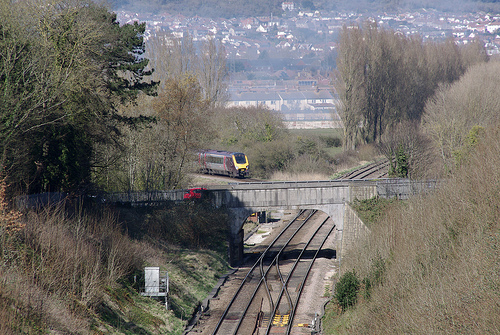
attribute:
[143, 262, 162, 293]
box — silver, metal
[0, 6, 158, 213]
trees — green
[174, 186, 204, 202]
train — red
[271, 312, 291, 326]
tool — yellow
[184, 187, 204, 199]
paint — red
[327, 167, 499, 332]
grass — tall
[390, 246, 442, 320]
plants — dried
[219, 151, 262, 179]
train — yellow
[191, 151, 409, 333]
railway — line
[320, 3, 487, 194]
trees — dead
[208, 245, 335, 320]
railway — line, metallic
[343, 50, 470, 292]
trees — grey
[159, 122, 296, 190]
train — grey